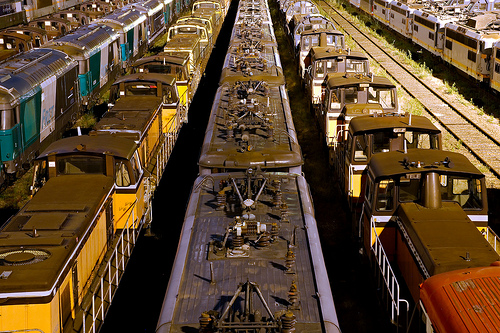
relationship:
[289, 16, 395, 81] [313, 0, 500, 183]
train on rail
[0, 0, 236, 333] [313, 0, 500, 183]
train on rail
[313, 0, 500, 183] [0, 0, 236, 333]
rail have train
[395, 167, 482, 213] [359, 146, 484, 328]
window built into train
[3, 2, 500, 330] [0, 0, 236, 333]
yard for train